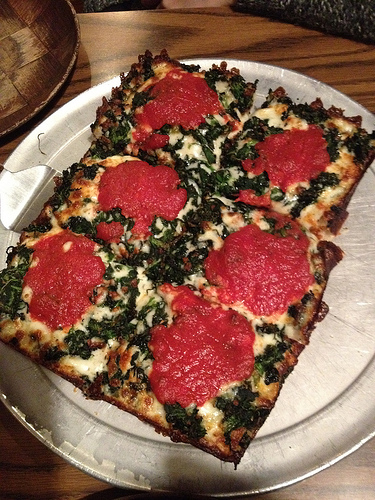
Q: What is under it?
A: A tray.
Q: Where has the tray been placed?
A: On the table.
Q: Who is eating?
A: No one.